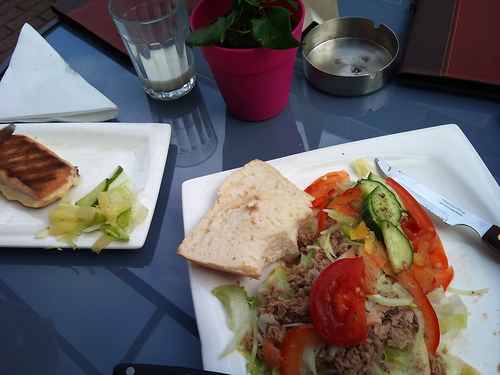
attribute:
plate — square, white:
[181, 120, 498, 373]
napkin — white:
[6, 17, 136, 125]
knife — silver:
[373, 138, 477, 249]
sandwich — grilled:
[2, 132, 66, 209]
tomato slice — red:
[313, 256, 369, 341]